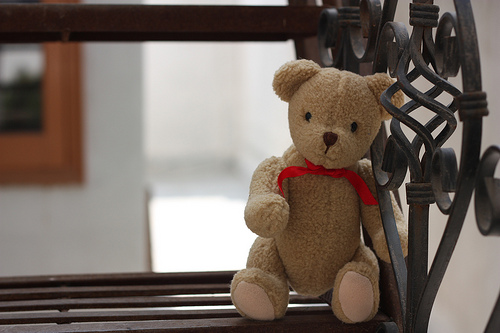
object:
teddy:
[227, 56, 411, 325]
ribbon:
[275, 158, 380, 207]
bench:
[0, 268, 396, 332]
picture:
[0, 43, 89, 187]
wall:
[0, 41, 146, 273]